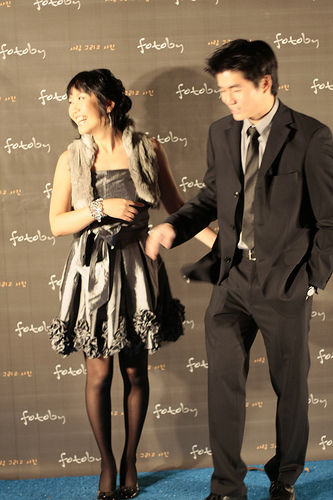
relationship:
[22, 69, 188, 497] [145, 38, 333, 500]
people standing next to he (man)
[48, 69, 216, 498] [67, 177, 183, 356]
people wears dress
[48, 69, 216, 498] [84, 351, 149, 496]
people wears stockings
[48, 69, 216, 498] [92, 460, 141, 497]
people wears heels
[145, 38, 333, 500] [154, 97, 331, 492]
he (man) wears suit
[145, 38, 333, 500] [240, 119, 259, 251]
he (man) wears a tie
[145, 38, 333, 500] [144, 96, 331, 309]
he (man) wears a suit jacket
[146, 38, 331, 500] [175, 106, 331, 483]
he (man) wears a suit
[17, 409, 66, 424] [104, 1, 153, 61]
text on backdrop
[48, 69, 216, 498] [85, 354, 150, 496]
people wearing hosiery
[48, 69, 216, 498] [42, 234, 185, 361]
people wearing dress